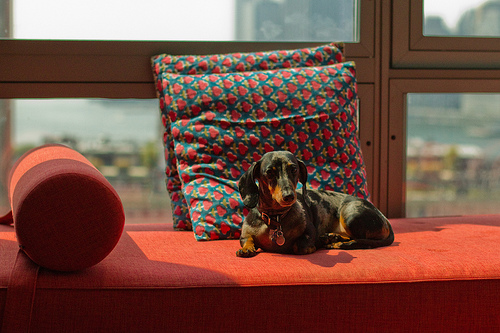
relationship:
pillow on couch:
[157, 61, 374, 247] [0, 147, 495, 331]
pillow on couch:
[155, 54, 382, 244] [1, 215, 498, 331]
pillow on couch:
[6, 143, 125, 273] [0, 147, 495, 331]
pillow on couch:
[6, 143, 125, 273] [1, 215, 498, 331]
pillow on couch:
[149, 40, 345, 231] [1, 215, 498, 331]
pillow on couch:
[146, 30, 350, 214] [1, 215, 498, 331]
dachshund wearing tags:
[234, 150, 394, 260] [268, 225, 284, 245]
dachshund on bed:
[237, 150, 394, 257] [1, 212, 498, 329]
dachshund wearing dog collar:
[237, 150, 394, 257] [256, 196, 298, 246]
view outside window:
[68, 117, 473, 187] [3, 2, 499, 220]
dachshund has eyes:
[234, 150, 394, 260] [250, 157, 291, 179]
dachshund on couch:
[234, 150, 394, 260] [4, 180, 498, 324]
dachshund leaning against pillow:
[234, 150, 394, 260] [149, 40, 345, 231]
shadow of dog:
[283, 248, 353, 270] [231, 144, 396, 263]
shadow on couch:
[283, 248, 353, 270] [1, 222, 496, 319]